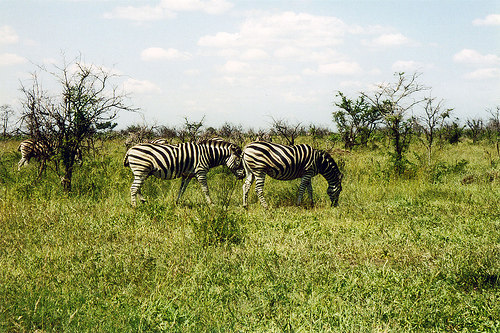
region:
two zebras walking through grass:
[110, 129, 355, 210]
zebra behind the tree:
[15, 134, 61, 181]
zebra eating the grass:
[235, 133, 348, 209]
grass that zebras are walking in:
[0, 125, 497, 330]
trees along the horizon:
[25, 75, 496, 184]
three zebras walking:
[1, 127, 353, 208]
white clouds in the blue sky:
[9, 15, 474, 123]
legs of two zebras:
[123, 170, 324, 207]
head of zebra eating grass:
[326, 173, 347, 212]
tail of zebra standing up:
[120, 155, 132, 170]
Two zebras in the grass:
[120, 140, 342, 208]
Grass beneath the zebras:
[143, 228, 430, 311]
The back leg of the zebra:
[123, 173, 145, 207]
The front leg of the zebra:
[291, 180, 321, 205]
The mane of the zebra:
[316, 144, 343, 166]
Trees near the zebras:
[341, 95, 436, 168]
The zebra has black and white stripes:
[146, 144, 198, 169]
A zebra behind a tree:
[21, 140, 56, 165]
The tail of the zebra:
[119, 150, 132, 166]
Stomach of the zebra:
[152, 165, 184, 180]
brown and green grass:
[1, 210, 493, 330]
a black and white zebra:
[113, 132, 243, 217]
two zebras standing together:
[121, 124, 345, 215]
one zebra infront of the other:
[110, 127, 345, 223]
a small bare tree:
[8, 64, 124, 202]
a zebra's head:
[213, 130, 250, 188]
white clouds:
[167, 33, 335, 103]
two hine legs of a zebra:
[239, 139, 274, 210]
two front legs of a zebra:
[173, 165, 221, 217]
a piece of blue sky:
[35, 10, 111, 54]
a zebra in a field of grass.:
[113, 112, 269, 216]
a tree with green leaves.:
[324, 56, 466, 179]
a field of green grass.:
[1, 138, 496, 331]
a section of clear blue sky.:
[61, 17, 131, 56]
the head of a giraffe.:
[320, 160, 355, 198]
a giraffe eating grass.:
[215, 120, 358, 205]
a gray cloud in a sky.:
[100, 0, 257, 31]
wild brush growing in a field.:
[0, 115, 499, 135]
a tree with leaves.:
[3, 68, 134, 191]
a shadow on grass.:
[449, 232, 498, 276]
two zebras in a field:
[104, 130, 361, 219]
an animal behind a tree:
[11, 46, 138, 216]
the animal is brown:
[15, 133, 57, 179]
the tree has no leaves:
[13, 45, 139, 185]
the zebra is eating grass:
[234, 134, 351, 216]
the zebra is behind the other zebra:
[106, 133, 263, 224]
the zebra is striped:
[120, 132, 250, 208]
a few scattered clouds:
[12, 1, 492, 129]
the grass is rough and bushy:
[5, 132, 497, 324]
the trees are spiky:
[0, 39, 499, 186]